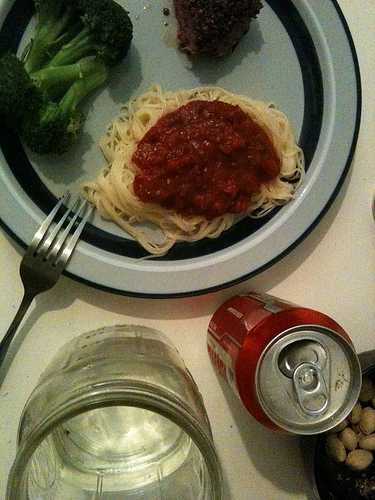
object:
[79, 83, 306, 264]
food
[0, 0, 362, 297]
table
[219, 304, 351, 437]
soda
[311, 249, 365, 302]
table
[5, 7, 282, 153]
food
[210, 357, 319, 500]
shadow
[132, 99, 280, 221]
red sauce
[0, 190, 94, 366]
fork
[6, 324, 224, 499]
glass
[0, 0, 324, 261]
rings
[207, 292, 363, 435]
can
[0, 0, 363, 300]
plate